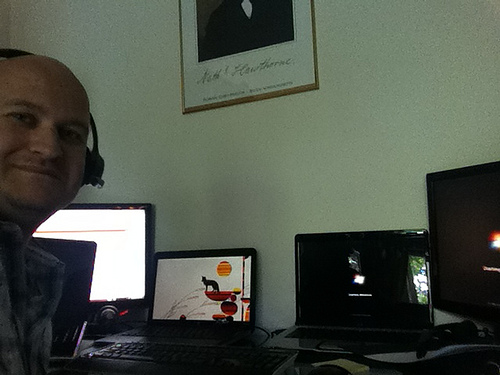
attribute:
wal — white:
[244, 116, 465, 213]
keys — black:
[138, 340, 192, 363]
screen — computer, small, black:
[149, 243, 259, 325]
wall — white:
[0, 0, 499, 329]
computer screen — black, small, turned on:
[39, 202, 154, 306]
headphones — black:
[79, 137, 116, 178]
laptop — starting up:
[260, 228, 435, 362]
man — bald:
[6, 49, 91, 241]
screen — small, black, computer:
[288, 227, 430, 317]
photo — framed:
[177, 0, 325, 116]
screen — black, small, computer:
[429, 182, 484, 264]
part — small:
[344, 125, 391, 196]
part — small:
[333, 98, 347, 148]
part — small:
[87, 22, 148, 100]